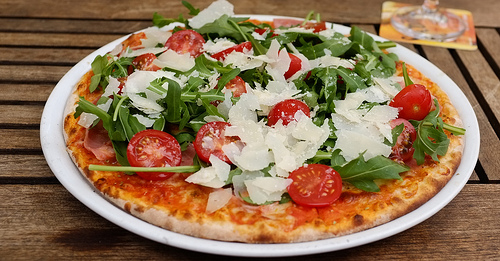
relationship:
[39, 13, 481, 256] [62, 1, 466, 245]
plate under pizza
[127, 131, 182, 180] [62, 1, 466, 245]
tomato slice on pizza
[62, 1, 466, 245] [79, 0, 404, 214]
pizza has sliced cheese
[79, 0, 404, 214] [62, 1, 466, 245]
sliced cheese on pizza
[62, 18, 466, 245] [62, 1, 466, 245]
crust around pizza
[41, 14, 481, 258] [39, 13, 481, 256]
rim of plate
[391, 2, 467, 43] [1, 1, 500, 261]
glass on table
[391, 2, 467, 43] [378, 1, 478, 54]
glass on coaster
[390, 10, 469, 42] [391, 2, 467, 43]
bottom of a glass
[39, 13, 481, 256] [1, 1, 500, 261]
plate on a table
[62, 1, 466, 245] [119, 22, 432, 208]
pizza has tomato slices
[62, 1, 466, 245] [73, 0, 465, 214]
pizza topped with vegetables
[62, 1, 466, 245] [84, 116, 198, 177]
pizza has sliced ham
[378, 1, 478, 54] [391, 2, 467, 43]
coaster under glass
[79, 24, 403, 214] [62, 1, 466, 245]
sliced cheese on pizza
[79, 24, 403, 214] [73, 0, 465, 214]
sliced cheese under vegetables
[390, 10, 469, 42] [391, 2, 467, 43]
bottom of glass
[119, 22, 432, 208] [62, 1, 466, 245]
tomato slices on pizza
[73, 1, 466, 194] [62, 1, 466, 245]
dandelions on pizza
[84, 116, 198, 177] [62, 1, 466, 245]
sliced ham on pizza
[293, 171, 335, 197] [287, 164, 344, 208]
seeds in tomato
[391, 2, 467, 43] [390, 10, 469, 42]
glass has a bottom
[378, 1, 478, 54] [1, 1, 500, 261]
coaster on table